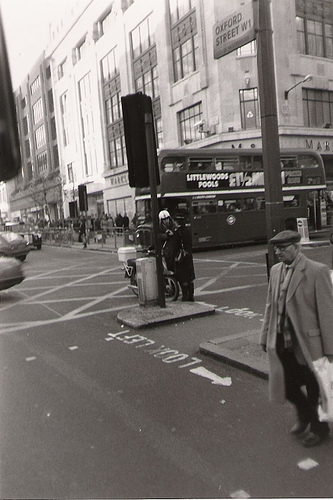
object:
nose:
[275, 247, 281, 255]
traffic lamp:
[284, 74, 312, 100]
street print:
[105, 329, 232, 387]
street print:
[215, 306, 263, 320]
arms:
[310, 255, 332, 356]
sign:
[212, 1, 256, 60]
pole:
[251, 0, 285, 280]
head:
[273, 232, 300, 262]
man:
[148, 210, 181, 252]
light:
[285, 74, 314, 100]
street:
[1, 323, 332, 495]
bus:
[134, 147, 327, 250]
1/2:
[240, 172, 252, 188]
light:
[121, 91, 161, 188]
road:
[0, 245, 333, 500]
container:
[117, 246, 136, 261]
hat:
[158, 209, 172, 224]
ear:
[293, 244, 299, 254]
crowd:
[35, 211, 130, 242]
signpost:
[211, 3, 256, 60]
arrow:
[189, 366, 232, 387]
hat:
[269, 230, 302, 245]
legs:
[302, 365, 330, 435]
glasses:
[272, 242, 295, 252]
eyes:
[280, 246, 284, 249]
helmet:
[158, 210, 170, 225]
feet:
[302, 430, 330, 448]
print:
[105, 330, 156, 349]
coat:
[164, 224, 197, 283]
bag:
[310, 356, 333, 422]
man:
[259, 229, 333, 447]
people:
[26, 211, 129, 241]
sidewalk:
[46, 228, 138, 252]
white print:
[190, 366, 233, 387]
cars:
[0, 216, 31, 261]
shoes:
[289, 417, 310, 435]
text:
[198, 180, 219, 188]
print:
[186, 172, 229, 188]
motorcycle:
[117, 241, 179, 302]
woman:
[172, 210, 198, 299]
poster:
[185, 169, 302, 190]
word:
[104, 330, 155, 348]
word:
[145, 345, 202, 369]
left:
[105, 327, 154, 348]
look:
[144, 344, 202, 368]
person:
[116, 213, 125, 236]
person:
[100, 214, 110, 243]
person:
[122, 213, 129, 231]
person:
[94, 214, 101, 243]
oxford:
[215, 12, 242, 34]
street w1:
[215, 12, 251, 47]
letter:
[105, 329, 203, 369]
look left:
[105, 329, 203, 368]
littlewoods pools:
[185, 170, 229, 189]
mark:
[104, 330, 155, 349]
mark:
[144, 345, 189, 364]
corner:
[100, 247, 150, 261]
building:
[0, 1, 333, 231]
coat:
[259, 254, 332, 404]